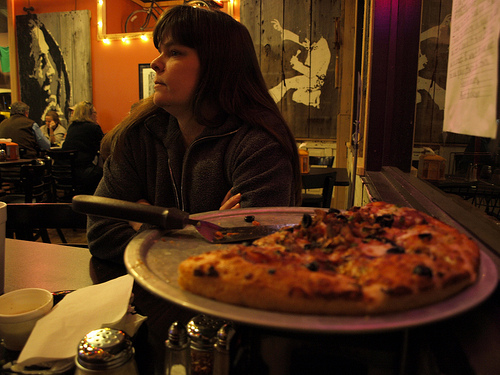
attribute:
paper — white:
[73, 299, 103, 321]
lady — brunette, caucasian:
[109, 27, 289, 259]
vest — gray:
[3, 113, 39, 158]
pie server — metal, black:
[71, 194, 303, 246]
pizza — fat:
[196, 166, 486, 331]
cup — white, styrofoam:
[1, 285, 56, 350]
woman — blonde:
[65, 92, 117, 192]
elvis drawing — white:
[267, 17, 331, 107]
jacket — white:
[31, 123, 66, 147]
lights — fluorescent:
[90, 1, 376, 61]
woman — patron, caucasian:
[86, 4, 306, 262]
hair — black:
[97, 2, 307, 202]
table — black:
[299, 167, 352, 202]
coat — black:
[92, 112, 293, 272]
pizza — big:
[173, 189, 490, 314]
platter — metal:
[118, 200, 498, 344]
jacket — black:
[99, 99, 301, 200]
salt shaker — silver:
[164, 320, 188, 372]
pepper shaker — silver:
[211, 320, 236, 371]